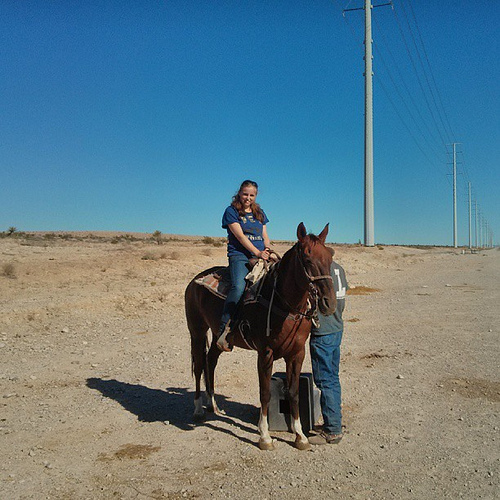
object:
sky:
[2, 1, 500, 242]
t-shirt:
[309, 260, 347, 335]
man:
[308, 247, 348, 445]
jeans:
[308, 332, 344, 433]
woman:
[217, 181, 279, 349]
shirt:
[222, 205, 269, 254]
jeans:
[223, 257, 267, 340]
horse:
[185, 222, 334, 451]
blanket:
[194, 270, 267, 303]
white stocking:
[205, 393, 219, 413]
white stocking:
[194, 396, 205, 421]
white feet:
[291, 415, 309, 451]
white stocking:
[259, 412, 276, 449]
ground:
[0, 242, 499, 500]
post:
[353, 1, 381, 241]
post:
[448, 139, 459, 245]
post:
[467, 180, 474, 247]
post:
[474, 198, 479, 249]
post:
[478, 204, 482, 247]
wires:
[370, 2, 463, 183]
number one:
[334, 268, 346, 300]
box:
[269, 371, 314, 433]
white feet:
[256, 410, 272, 450]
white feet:
[208, 394, 223, 414]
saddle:
[223, 252, 278, 281]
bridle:
[295, 249, 335, 289]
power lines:
[335, 0, 494, 245]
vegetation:
[2, 225, 213, 244]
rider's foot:
[216, 335, 232, 351]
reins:
[258, 252, 320, 324]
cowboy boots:
[308, 432, 343, 444]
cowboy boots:
[313, 423, 328, 432]